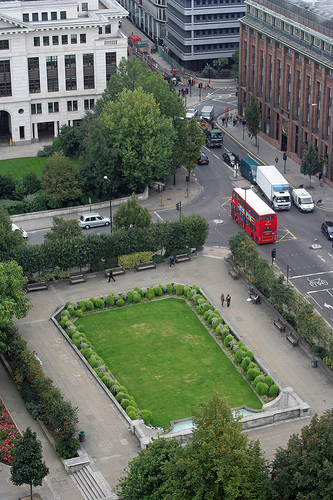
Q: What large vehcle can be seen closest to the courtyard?
A: A double-decker bus.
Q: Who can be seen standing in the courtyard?
A: Humans.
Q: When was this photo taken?
A: Daytime.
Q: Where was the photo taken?
A: A city.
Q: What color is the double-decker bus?
A: Red.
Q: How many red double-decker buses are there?
A: One.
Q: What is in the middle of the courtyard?
A: Grass.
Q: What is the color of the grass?
A: Green.